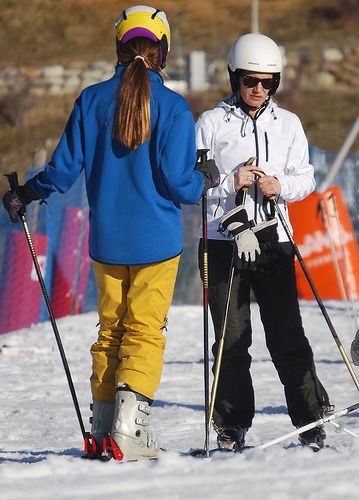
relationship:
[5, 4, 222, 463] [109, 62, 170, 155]
girl has ponytail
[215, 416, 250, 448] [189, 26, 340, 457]
ski boot of woman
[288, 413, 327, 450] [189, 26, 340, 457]
ski boot of woman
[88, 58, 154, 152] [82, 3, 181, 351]
ponytail of woman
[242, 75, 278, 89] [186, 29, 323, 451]
glasses of woman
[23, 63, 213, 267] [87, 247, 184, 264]
jacket with trim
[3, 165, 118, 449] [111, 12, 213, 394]
pole of woman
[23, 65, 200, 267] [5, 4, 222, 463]
sweater of girl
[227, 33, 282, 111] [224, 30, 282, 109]
helmet on man head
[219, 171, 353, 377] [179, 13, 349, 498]
poles of man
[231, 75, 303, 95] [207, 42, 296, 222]
glasses of man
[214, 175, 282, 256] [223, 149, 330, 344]
gloves hanging from skis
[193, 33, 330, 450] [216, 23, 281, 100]
girl with helmet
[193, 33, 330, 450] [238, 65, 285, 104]
girl with sunglasses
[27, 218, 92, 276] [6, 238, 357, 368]
barrier on course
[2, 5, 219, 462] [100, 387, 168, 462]
girl wearing boots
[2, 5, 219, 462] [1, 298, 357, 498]
girl at ski slope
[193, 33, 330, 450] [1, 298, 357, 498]
girl at ski slope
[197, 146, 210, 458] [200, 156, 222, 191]
ski pole in woman's hand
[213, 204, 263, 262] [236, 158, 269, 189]
glove in woman's hand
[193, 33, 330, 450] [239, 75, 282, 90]
girl wearing sunglasses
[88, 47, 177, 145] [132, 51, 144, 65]
ponytail held by ponytail holder